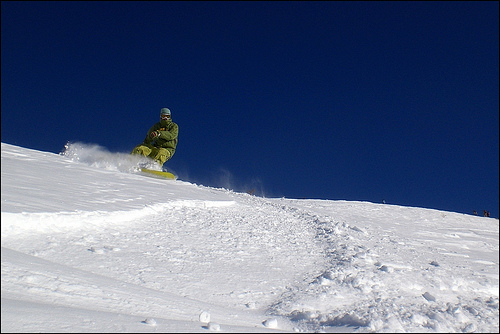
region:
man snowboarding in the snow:
[111, 78, 216, 184]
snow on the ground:
[158, 203, 269, 273]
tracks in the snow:
[294, 202, 394, 273]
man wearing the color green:
[125, 93, 205, 186]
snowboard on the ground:
[138, 162, 182, 197]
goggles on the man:
[152, 97, 182, 122]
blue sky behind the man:
[256, 78, 356, 139]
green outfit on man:
[135, 116, 185, 153]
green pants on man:
[122, 144, 175, 157]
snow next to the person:
[85, 137, 134, 178]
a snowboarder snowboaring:
[138, 103, 179, 180]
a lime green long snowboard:
[137, 163, 177, 180]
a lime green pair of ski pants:
[130, 143, 173, 165]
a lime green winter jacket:
[147, 119, 179, 148]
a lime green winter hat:
[159, 104, 173, 114]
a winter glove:
[152, 128, 158, 135]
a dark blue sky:
[2, 4, 496, 223]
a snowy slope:
[0, 139, 498, 326]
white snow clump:
[197, 308, 210, 320]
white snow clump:
[264, 316, 282, 328]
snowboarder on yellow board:
[128, 102, 215, 191]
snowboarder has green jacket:
[136, 113, 214, 165]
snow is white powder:
[27, 128, 366, 284]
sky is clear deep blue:
[58, 15, 488, 212]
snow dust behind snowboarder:
[41, 132, 191, 209]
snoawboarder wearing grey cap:
[153, 95, 191, 135]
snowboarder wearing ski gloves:
[141, 125, 177, 154]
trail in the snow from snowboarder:
[162, 176, 274, 331]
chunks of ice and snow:
[142, 299, 272, 331]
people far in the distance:
[383, 186, 498, 234]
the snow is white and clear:
[104, 198, 242, 329]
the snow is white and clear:
[191, 196, 278, 318]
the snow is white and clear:
[255, 197, 320, 323]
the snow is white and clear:
[173, 118, 318, 314]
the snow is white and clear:
[219, 183, 310, 318]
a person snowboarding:
[128, 105, 185, 177]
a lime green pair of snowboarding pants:
[134, 144, 166, 167]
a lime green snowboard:
[136, 161, 178, 181]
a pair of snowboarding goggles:
[159, 111, 169, 118]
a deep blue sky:
[3, 3, 496, 220]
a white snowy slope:
[2, 142, 497, 332]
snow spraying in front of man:
[59, 138, 158, 170]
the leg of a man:
[150, 143, 169, 168]